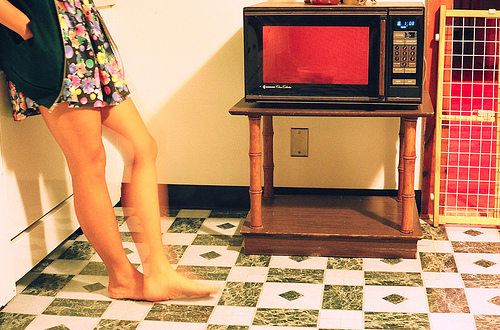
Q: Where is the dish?
A: In microwave.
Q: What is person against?
A: Cabinet.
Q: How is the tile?
A: Checkered.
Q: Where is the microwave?
A: On table.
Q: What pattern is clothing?
A: Floral.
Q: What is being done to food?
A: Microwaved.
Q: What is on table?
A: Microwave.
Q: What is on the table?
A: Microwave.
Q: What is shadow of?
A: A woman.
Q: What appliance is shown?
A: Microwave.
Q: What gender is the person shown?
A: Female.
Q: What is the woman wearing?
A: Dress.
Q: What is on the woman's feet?
A: Nothing.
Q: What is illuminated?
A: The microwave.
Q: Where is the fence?
A: In front of the doorway.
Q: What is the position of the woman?
A: Leaning.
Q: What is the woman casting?
A: A shadow.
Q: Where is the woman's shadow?
A: Wall and floor.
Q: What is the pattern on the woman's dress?
A: Floral.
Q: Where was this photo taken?
A: In the kitchen.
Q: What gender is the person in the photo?
A: Female.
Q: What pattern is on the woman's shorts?
A: Floral.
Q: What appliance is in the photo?
A: A microwave.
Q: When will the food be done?
A: Within a minute.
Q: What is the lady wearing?
A: A printed short dress.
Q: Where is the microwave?
A: On a small table.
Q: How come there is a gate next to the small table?
A: To prevent the dog going to the kitchen.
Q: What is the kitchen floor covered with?
A: Tiles.